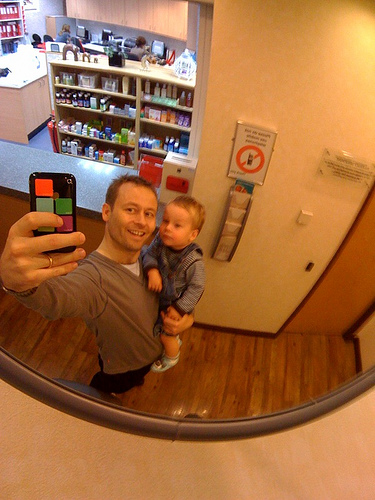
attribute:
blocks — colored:
[34, 175, 74, 242]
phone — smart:
[26, 169, 80, 258]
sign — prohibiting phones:
[228, 121, 280, 186]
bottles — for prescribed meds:
[56, 90, 90, 110]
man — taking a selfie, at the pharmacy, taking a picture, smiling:
[1, 173, 198, 401]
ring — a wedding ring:
[46, 254, 56, 271]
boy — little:
[142, 196, 205, 376]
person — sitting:
[56, 22, 77, 45]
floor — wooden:
[2, 283, 369, 424]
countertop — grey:
[1, 140, 180, 233]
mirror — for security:
[1, 1, 375, 443]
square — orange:
[33, 178, 56, 199]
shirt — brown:
[2, 249, 168, 373]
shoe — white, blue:
[149, 356, 179, 373]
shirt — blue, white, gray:
[142, 238, 211, 316]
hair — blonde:
[170, 196, 213, 232]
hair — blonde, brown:
[104, 174, 158, 208]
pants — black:
[94, 355, 153, 396]